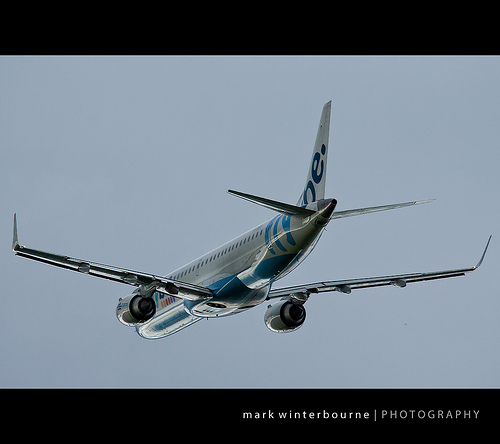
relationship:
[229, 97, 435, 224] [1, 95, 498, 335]
tail on airplane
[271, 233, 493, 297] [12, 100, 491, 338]
wing on plane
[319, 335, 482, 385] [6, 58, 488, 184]
clouds in sky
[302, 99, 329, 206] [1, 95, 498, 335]
fin on airplane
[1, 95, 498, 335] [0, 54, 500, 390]
airplane in sky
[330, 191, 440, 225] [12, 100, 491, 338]
wing on plane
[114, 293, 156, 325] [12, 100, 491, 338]
engine on plane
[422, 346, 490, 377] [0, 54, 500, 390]
clouds in sky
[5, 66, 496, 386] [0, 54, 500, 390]
clouds in sky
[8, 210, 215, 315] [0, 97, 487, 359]
wing on plane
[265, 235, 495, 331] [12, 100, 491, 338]
wing on plane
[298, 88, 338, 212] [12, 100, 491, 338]
tail on plane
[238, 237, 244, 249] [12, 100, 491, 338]
windows on plane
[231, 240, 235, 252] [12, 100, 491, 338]
windows on plane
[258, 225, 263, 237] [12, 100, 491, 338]
windows on plane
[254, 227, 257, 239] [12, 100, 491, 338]
windows on plane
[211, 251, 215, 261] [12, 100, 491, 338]
windows on plane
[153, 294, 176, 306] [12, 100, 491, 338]
row on plane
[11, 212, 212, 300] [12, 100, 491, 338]
wing on plane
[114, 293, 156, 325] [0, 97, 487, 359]
engine on plane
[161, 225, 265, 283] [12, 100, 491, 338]
windows are on plane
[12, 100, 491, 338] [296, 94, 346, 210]
plane has tail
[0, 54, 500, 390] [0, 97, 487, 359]
sky above plane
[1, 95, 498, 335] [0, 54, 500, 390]
airplane flying though sky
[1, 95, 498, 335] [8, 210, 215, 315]
airplane has wing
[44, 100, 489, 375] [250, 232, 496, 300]
jet has wing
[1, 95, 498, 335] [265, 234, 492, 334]
airplane has right wing